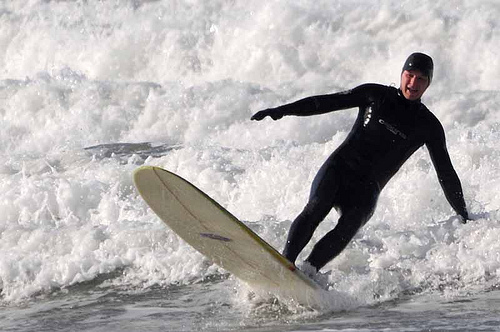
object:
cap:
[400, 52, 434, 89]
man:
[250, 47, 472, 284]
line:
[153, 165, 279, 296]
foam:
[0, 148, 130, 298]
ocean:
[0, 0, 497, 332]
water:
[0, 0, 498, 328]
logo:
[198, 231, 233, 244]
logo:
[378, 119, 408, 141]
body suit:
[239, 84, 471, 267]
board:
[132, 165, 337, 310]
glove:
[251, 107, 283, 122]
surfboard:
[124, 159, 337, 312]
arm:
[281, 82, 379, 118]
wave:
[7, 7, 137, 285]